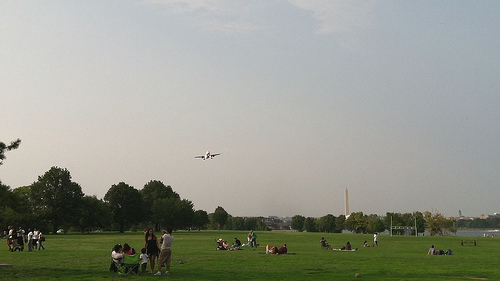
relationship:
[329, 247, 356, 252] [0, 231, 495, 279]
blanket on ground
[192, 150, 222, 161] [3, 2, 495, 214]
airplane in sky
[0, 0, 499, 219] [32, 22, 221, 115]
cloud in blue sky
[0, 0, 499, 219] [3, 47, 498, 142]
cloud in blue sky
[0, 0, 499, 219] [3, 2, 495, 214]
cloud in sky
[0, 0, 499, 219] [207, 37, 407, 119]
cloud in sky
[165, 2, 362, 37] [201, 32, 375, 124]
cloud in sky